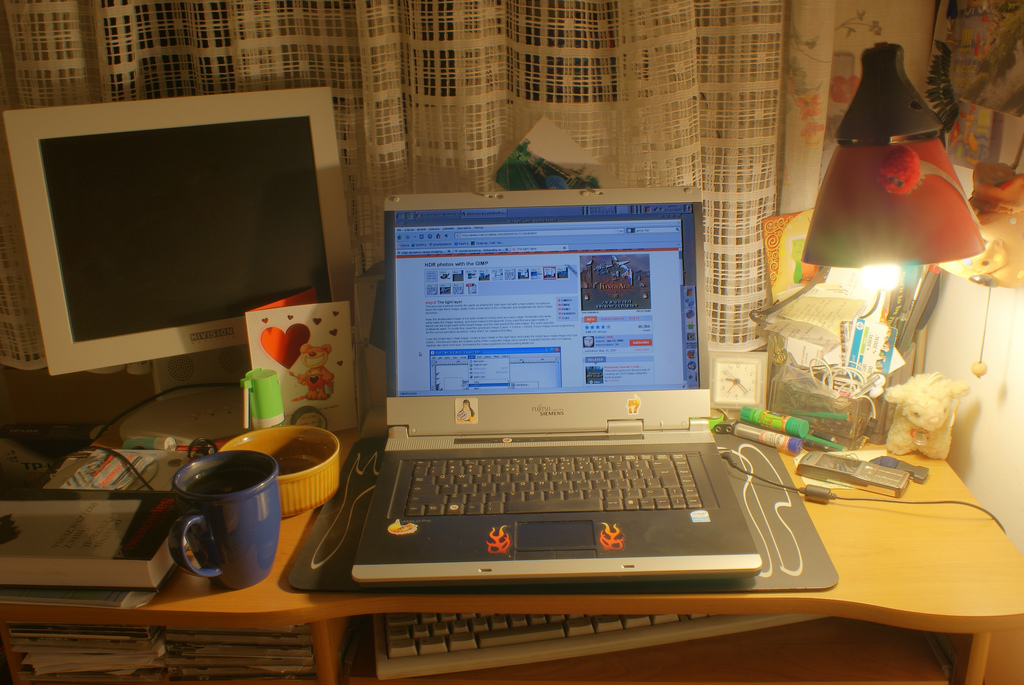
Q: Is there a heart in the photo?
A: Yes, there is a heart.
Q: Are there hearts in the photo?
A: Yes, there is a heart.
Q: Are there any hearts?
A: Yes, there is a heart.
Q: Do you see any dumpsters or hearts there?
A: Yes, there is a heart.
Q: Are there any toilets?
A: No, there are no toilets.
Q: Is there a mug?
A: Yes, there is a mug.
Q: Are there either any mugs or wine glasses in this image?
A: Yes, there is a mug.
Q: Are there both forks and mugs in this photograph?
A: No, there is a mug but no forks.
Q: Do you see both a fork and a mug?
A: No, there is a mug but no forks.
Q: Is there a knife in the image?
A: No, there are no knives.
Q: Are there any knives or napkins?
A: No, there are no knives or napkins.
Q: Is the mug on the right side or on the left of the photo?
A: The mug is on the left of the image.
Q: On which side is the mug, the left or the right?
A: The mug is on the left of the image.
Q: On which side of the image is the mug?
A: The mug is on the left of the image.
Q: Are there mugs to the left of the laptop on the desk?
A: Yes, there is a mug to the left of the laptop.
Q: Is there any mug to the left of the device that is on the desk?
A: Yes, there is a mug to the left of the laptop.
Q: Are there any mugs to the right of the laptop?
A: No, the mug is to the left of the laptop.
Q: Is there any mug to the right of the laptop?
A: No, the mug is to the left of the laptop.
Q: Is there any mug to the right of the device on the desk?
A: No, the mug is to the left of the laptop.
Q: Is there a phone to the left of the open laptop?
A: No, there is a mug to the left of the laptop.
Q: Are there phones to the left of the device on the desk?
A: No, there is a mug to the left of the laptop.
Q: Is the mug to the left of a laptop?
A: Yes, the mug is to the left of a laptop.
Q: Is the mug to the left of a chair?
A: No, the mug is to the left of a laptop.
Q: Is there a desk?
A: Yes, there is a desk.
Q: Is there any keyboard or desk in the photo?
A: Yes, there is a desk.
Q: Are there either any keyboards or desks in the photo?
A: Yes, there is a desk.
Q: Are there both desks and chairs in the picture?
A: No, there is a desk but no chairs.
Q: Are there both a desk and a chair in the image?
A: No, there is a desk but no chairs.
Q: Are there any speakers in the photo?
A: No, there are no speakers.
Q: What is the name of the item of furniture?
A: The piece of furniture is a desk.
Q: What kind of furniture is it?
A: The piece of furniture is a desk.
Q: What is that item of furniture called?
A: This is a desk.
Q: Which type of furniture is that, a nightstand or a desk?
A: This is a desk.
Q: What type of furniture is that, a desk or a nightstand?
A: This is a desk.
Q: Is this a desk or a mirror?
A: This is a desk.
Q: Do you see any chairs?
A: No, there are no chairs.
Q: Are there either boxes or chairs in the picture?
A: No, there are no chairs or boxes.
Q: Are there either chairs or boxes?
A: No, there are no chairs or boxes.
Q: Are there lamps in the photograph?
A: Yes, there is a lamp.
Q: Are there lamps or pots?
A: Yes, there is a lamp.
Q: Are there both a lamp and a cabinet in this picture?
A: No, there is a lamp but no cabinets.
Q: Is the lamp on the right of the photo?
A: Yes, the lamp is on the right of the image.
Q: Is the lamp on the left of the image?
A: No, the lamp is on the right of the image.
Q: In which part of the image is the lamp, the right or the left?
A: The lamp is on the right of the image.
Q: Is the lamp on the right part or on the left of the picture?
A: The lamp is on the right of the image.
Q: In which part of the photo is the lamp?
A: The lamp is on the right of the image.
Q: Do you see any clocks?
A: Yes, there is a clock.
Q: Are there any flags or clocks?
A: Yes, there is a clock.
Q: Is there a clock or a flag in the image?
A: Yes, there is a clock.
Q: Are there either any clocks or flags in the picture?
A: Yes, there is a clock.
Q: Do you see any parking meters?
A: No, there are no parking meters.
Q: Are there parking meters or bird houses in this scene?
A: No, there are no parking meters or bird houses.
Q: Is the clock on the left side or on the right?
A: The clock is on the right of the image.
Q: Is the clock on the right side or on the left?
A: The clock is on the right of the image.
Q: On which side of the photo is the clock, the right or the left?
A: The clock is on the right of the image.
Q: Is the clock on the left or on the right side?
A: The clock is on the right of the image.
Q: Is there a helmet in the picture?
A: No, there are no helmets.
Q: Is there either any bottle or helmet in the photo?
A: No, there are no helmets or bottles.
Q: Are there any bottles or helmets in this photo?
A: No, there are no helmets or bottles.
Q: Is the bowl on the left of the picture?
A: Yes, the bowl is on the left of the image.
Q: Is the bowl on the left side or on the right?
A: The bowl is on the left of the image.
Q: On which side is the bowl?
A: The bowl is on the left of the image.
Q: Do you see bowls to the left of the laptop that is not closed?
A: Yes, there is a bowl to the left of the laptop computer.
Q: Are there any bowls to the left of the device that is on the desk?
A: Yes, there is a bowl to the left of the laptop computer.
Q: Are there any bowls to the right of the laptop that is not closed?
A: No, the bowl is to the left of the laptop.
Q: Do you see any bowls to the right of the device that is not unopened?
A: No, the bowl is to the left of the laptop.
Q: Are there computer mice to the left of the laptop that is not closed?
A: No, there is a bowl to the left of the laptop.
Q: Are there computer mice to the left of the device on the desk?
A: No, there is a bowl to the left of the laptop.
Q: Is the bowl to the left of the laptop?
A: Yes, the bowl is to the left of the laptop.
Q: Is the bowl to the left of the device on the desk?
A: Yes, the bowl is to the left of the laptop.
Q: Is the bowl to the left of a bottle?
A: No, the bowl is to the left of the laptop.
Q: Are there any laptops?
A: Yes, there is a laptop.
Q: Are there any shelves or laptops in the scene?
A: Yes, there is a laptop.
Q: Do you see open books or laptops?
A: Yes, there is an open laptop.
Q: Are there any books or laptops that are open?
A: Yes, the laptop is open.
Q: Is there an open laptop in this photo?
A: Yes, there is an open laptop.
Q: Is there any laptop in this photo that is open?
A: Yes, there is a laptop that is open.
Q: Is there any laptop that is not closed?
A: Yes, there is a open laptop.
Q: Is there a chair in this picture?
A: No, there are no chairs.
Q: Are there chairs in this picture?
A: No, there are no chairs.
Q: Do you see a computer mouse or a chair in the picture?
A: No, there are no chairs or computer mice.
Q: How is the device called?
A: The device is a laptop.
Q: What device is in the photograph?
A: The device is a laptop.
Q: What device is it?
A: The device is a laptop.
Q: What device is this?
A: This is a laptop.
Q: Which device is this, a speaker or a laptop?
A: This is a laptop.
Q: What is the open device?
A: The device is a laptop.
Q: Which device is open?
A: The device is a laptop.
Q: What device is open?
A: The device is a laptop.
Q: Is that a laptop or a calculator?
A: That is a laptop.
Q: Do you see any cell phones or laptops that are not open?
A: No, there is a laptop but it is open.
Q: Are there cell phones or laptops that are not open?
A: No, there is a laptop but it is open.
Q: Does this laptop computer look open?
A: Yes, the laptop computer is open.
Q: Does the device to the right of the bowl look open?
A: Yes, the laptop computer is open.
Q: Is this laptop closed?
A: No, the laptop is open.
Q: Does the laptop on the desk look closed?
A: No, the laptop is open.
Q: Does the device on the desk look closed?
A: No, the laptop is open.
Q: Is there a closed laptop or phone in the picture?
A: No, there is a laptop but it is open.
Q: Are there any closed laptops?
A: No, there is a laptop but it is open.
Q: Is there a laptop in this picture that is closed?
A: No, there is a laptop but it is open.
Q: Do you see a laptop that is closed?
A: No, there is a laptop but it is open.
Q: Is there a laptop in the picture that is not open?
A: No, there is a laptop but it is open.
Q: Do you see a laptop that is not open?
A: No, there is a laptop but it is open.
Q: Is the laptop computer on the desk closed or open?
A: The laptop is open.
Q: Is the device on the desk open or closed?
A: The laptop is open.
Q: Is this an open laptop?
A: Yes, this is an open laptop.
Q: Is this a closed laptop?
A: No, this is an open laptop.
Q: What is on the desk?
A: The laptop is on the desk.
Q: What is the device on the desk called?
A: The device is a laptop.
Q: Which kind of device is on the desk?
A: The device is a laptop.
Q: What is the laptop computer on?
A: The laptop computer is on the desk.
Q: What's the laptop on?
A: The laptop computer is on the desk.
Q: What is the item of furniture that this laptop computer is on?
A: The piece of furniture is a desk.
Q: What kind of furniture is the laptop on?
A: The laptop computer is on the desk.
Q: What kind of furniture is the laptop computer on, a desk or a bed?
A: The laptop computer is on a desk.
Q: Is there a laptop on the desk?
A: Yes, there is a laptop on the desk.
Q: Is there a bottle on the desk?
A: No, there is a laptop on the desk.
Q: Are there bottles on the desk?
A: No, there is a laptop on the desk.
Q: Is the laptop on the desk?
A: Yes, the laptop is on the desk.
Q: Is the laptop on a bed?
A: No, the laptop is on the desk.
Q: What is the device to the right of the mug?
A: The device is a laptop.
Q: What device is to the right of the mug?
A: The device is a laptop.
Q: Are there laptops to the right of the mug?
A: Yes, there is a laptop to the right of the mug.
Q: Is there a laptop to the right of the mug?
A: Yes, there is a laptop to the right of the mug.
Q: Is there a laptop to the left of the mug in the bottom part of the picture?
A: No, the laptop is to the right of the mug.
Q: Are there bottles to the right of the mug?
A: No, there is a laptop to the right of the mug.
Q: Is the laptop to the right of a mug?
A: Yes, the laptop is to the right of a mug.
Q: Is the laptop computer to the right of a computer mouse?
A: No, the laptop computer is to the right of a mug.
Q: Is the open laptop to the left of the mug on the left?
A: No, the laptop is to the right of the mug.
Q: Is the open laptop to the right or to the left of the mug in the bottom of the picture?
A: The laptop is to the right of the mug.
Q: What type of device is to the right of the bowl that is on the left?
A: The device is a laptop.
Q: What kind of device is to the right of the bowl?
A: The device is a laptop.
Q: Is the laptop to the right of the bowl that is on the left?
A: Yes, the laptop is to the right of the bowl.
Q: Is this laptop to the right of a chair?
A: No, the laptop is to the right of the bowl.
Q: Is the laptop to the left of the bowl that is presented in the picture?
A: No, the laptop is to the right of the bowl.